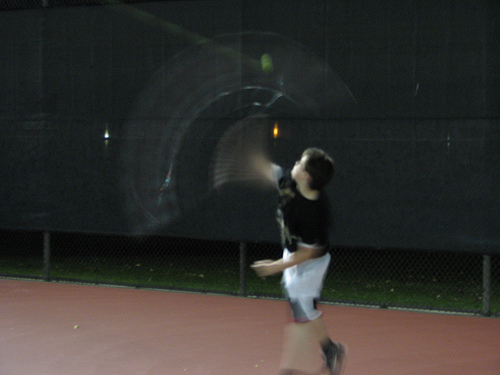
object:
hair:
[302, 147, 338, 191]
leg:
[280, 261, 329, 344]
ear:
[301, 171, 313, 182]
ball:
[258, 51, 275, 73]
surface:
[0, 256, 500, 374]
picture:
[1, 1, 500, 373]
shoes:
[315, 336, 346, 373]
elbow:
[303, 242, 324, 257]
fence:
[0, 226, 500, 318]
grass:
[0, 245, 500, 318]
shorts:
[278, 247, 331, 326]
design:
[311, 296, 323, 313]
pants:
[278, 242, 332, 326]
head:
[289, 146, 334, 187]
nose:
[291, 160, 301, 167]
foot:
[318, 339, 345, 374]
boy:
[208, 113, 350, 374]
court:
[0, 249, 500, 375]